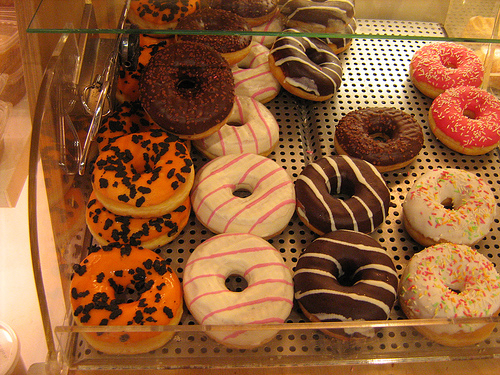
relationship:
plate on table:
[17, 28, 56, 46] [174, 16, 217, 49]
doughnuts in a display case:
[209, 59, 280, 210] [22, 26, 499, 228]